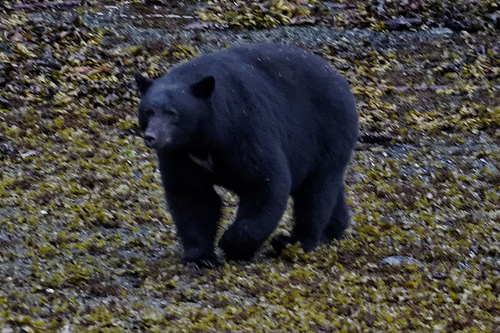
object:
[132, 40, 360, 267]
bear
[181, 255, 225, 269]
paw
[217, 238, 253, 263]
paw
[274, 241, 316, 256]
paw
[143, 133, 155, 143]
nose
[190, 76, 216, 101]
ear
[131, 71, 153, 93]
ear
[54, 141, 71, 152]
leaves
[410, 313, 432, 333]
leaves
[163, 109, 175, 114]
eye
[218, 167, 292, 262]
leg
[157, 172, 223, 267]
leg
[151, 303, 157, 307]
rocks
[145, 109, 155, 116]
eye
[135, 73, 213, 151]
head